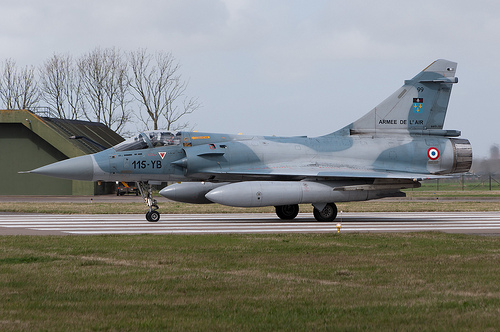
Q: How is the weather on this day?
A: It is overcast.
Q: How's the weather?
A: It is overcast.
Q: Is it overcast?
A: Yes, it is overcast.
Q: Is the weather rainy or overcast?
A: It is overcast.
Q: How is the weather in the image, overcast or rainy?
A: It is overcast.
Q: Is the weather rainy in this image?
A: No, it is overcast.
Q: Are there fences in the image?
A: No, there are no fences.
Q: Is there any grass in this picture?
A: Yes, there is grass.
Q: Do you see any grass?
A: Yes, there is grass.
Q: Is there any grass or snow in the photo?
A: Yes, there is grass.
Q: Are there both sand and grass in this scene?
A: No, there is grass but no sand.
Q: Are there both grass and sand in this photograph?
A: No, there is grass but no sand.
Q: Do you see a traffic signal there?
A: No, there are no traffic lights.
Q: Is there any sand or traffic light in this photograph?
A: No, there are no traffic lights or sand.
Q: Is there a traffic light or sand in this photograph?
A: No, there are no traffic lights or sand.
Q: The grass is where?
A: The grass is on the ground.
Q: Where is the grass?
A: The grass is on the ground.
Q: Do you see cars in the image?
A: No, there are no cars.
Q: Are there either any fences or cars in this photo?
A: No, there are no cars or fences.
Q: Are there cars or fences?
A: No, there are no cars or fences.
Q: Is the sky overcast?
A: Yes, the sky is overcast.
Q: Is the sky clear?
A: No, the sky is overcast.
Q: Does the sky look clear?
A: No, the sky is overcast.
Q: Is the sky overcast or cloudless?
A: The sky is overcast.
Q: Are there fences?
A: No, there are no fences.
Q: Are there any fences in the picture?
A: No, there are no fences.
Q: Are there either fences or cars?
A: No, there are no fences or cars.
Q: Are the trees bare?
A: Yes, the trees are bare.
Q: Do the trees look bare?
A: Yes, the trees are bare.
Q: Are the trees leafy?
A: No, the trees are bare.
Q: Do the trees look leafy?
A: No, the trees are bare.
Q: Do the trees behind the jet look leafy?
A: No, the trees are bare.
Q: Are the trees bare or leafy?
A: The trees are bare.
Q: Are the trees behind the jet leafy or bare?
A: The trees are bare.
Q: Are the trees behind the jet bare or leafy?
A: The trees are bare.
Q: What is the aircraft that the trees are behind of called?
A: The aircraft is a jet.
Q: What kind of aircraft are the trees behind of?
A: The trees are behind the jet.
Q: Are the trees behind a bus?
A: No, the trees are behind the jet.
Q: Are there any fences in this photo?
A: No, there are no fences.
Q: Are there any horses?
A: No, there are no horses.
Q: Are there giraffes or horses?
A: No, there are no horses or giraffes.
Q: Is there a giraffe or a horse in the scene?
A: No, there are no horses or giraffes.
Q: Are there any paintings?
A: No, there are no paintings.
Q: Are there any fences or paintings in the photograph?
A: No, there are no paintings or fences.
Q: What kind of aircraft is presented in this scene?
A: The aircraft is a jet.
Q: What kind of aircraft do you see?
A: The aircraft is a jet.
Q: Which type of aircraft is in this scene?
A: The aircraft is a jet.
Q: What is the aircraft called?
A: The aircraft is a jet.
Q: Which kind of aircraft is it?
A: The aircraft is a jet.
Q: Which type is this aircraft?
A: That is a jet.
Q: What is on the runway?
A: The jet is on the runway.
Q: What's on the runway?
A: The jet is on the runway.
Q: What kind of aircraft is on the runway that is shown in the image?
A: The aircraft is a jet.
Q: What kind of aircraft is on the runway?
A: The aircraft is a jet.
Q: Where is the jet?
A: The jet is on the runway.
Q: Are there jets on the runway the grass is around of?
A: Yes, there is a jet on the runway.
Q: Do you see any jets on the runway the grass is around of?
A: Yes, there is a jet on the runway.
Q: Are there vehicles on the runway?
A: No, there is a jet on the runway.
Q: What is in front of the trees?
A: The jet is in front of the trees.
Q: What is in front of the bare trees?
A: The jet is in front of the trees.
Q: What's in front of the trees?
A: The jet is in front of the trees.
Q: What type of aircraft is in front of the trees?
A: The aircraft is a jet.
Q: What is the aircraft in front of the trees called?
A: The aircraft is a jet.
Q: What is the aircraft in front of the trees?
A: The aircraft is a jet.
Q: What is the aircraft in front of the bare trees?
A: The aircraft is a jet.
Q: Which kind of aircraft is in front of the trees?
A: The aircraft is a jet.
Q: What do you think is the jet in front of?
A: The jet is in front of the trees.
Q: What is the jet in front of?
A: The jet is in front of the trees.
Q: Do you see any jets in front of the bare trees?
A: Yes, there is a jet in front of the trees.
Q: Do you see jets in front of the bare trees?
A: Yes, there is a jet in front of the trees.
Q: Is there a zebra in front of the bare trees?
A: No, there is a jet in front of the trees.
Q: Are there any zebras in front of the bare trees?
A: No, there is a jet in front of the trees.